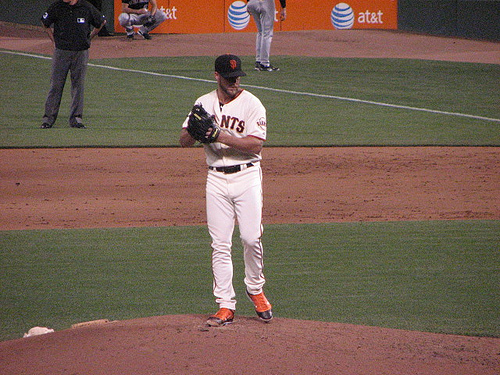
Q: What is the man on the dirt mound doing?
A: Pitching.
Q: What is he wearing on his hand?
A: A baseball glove.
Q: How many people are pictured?
A: Four.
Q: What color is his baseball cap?
A: Black.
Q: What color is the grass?
A: Green.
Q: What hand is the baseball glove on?
A: His left.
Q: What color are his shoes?
A: Orange.